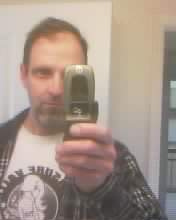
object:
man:
[0, 16, 168, 219]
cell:
[61, 66, 95, 153]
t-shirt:
[0, 125, 76, 220]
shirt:
[0, 106, 168, 218]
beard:
[31, 91, 65, 126]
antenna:
[92, 101, 99, 118]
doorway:
[157, 26, 175, 219]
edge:
[156, 29, 173, 217]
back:
[66, 74, 91, 122]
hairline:
[30, 31, 79, 56]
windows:
[167, 80, 175, 110]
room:
[164, 76, 176, 190]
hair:
[21, 15, 88, 63]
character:
[19, 166, 48, 219]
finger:
[68, 121, 113, 143]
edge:
[82, 121, 107, 128]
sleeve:
[68, 141, 169, 220]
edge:
[86, 172, 115, 196]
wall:
[104, 1, 167, 163]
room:
[155, 20, 172, 219]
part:
[98, 127, 110, 137]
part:
[2, 163, 65, 218]